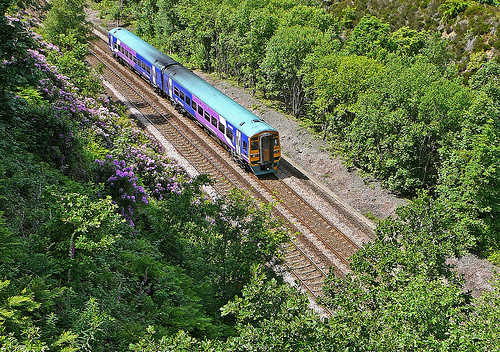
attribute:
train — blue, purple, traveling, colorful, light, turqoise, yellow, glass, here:
[139, 55, 283, 173]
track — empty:
[267, 175, 375, 272]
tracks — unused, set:
[256, 182, 372, 322]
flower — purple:
[96, 140, 155, 199]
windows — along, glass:
[121, 47, 165, 68]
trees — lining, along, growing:
[276, 43, 415, 150]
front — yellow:
[241, 123, 282, 160]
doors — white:
[222, 124, 250, 165]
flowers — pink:
[104, 127, 193, 235]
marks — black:
[236, 111, 273, 138]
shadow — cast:
[129, 91, 183, 128]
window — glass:
[215, 116, 244, 134]